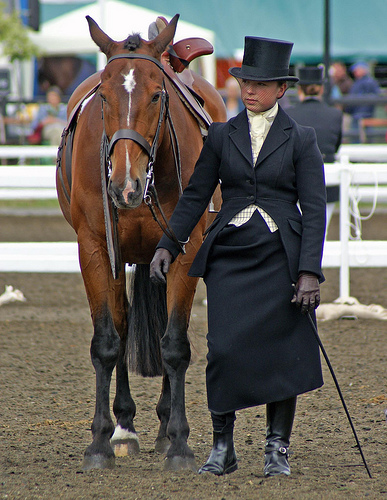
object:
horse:
[49, 14, 210, 457]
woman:
[149, 32, 337, 480]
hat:
[230, 33, 300, 85]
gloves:
[286, 264, 324, 315]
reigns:
[68, 53, 186, 278]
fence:
[4, 140, 60, 278]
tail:
[117, 256, 168, 377]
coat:
[158, 108, 348, 293]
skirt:
[192, 210, 334, 405]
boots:
[192, 371, 303, 479]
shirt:
[243, 112, 270, 154]